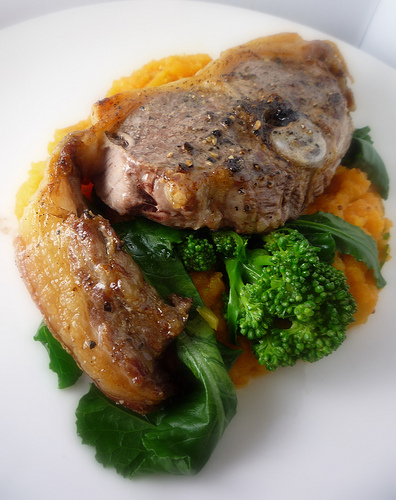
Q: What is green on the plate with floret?
A: Broccoli.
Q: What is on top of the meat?
A: Seasoning.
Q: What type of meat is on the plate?
A: Steak.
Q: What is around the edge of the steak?
A: Fat.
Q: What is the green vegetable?
A: Broccoli.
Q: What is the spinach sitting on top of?
A: Plate.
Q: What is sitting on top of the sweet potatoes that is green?
A: Broccoli.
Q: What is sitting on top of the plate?
A: Food.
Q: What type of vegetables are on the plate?
A: Broccoli and spinach.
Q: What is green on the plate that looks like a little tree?
A: Broccoli.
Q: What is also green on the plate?
A: Lettuce.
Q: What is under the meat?
A: Mashed sweet potatoes.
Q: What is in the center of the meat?
A: A bone.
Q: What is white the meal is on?
A: The plate.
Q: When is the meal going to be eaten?
A: For dinner.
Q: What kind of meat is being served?
A: Beef.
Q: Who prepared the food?
A: A chef.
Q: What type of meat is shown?
A: Steak.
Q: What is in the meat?
A: Bone.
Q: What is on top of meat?
A: Seasoning.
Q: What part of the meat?
A: Fatty.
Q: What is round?
A: Plate.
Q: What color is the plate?
A: White.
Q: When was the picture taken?
A: Daytime.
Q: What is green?
A: Broccoli.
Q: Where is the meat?
A: Top.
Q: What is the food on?
A: Plate.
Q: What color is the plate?
A: White.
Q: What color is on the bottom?
A: Yellow.